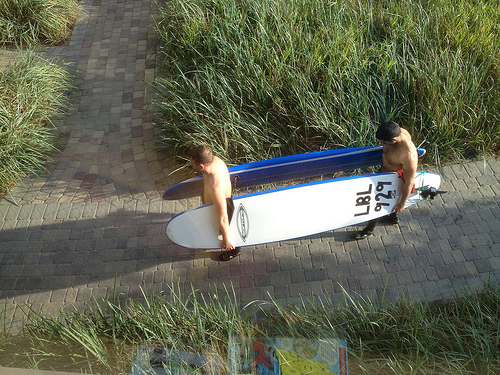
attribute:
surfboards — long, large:
[159, 166, 448, 258]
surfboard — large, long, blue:
[164, 144, 433, 193]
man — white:
[193, 139, 238, 255]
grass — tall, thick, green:
[152, 6, 499, 129]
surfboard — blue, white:
[157, 135, 435, 202]